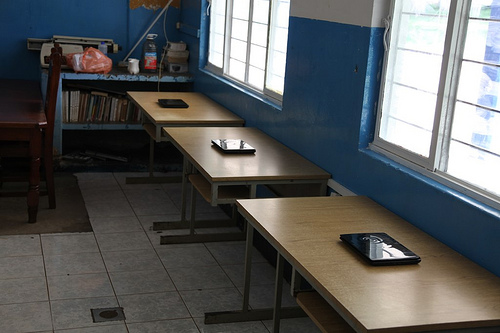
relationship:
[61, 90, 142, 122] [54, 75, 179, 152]
books on shelf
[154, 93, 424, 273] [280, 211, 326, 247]
taptops on table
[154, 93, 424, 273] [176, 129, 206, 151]
taptops on table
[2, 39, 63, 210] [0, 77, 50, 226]
chair in front of table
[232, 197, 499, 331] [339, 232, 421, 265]
desk with laptop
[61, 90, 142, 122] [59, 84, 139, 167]
books on bookshelf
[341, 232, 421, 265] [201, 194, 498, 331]
laptop on table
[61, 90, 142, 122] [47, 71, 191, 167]
books on bookshelf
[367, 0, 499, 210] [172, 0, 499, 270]
window on wall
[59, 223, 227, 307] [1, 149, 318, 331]
tile on floor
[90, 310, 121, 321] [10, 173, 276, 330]
drain in floor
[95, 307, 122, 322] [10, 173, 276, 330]
drain in floor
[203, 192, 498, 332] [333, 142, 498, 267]
wooden desk against wall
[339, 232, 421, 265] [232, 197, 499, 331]
laptop on desk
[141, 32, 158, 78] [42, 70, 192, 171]
juice on bookshelf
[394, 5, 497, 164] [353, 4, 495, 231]
bars on windows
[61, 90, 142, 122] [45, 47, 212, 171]
books on shelf